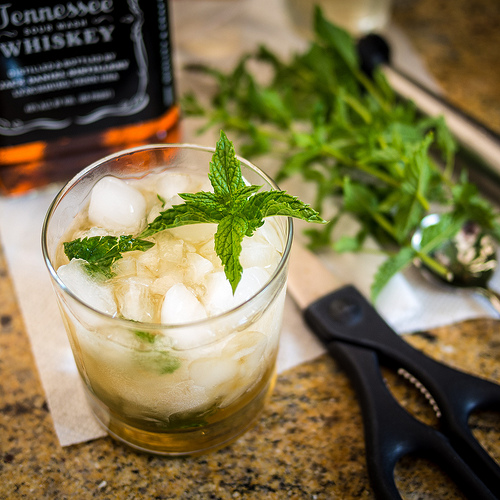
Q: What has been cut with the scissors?
A: Mint.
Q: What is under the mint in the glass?
A: Ice.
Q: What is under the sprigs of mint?
A: Paper.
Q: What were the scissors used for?
A: Cut peppermint.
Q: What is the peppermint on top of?
A: Ice cubes.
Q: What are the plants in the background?
A: Peppermint plants.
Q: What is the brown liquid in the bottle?
A: Whiskey.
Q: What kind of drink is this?
A: Whiskey on the rocks.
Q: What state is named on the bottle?
A: Tennessee.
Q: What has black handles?
A: Scissors.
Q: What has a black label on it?
A: Bottle.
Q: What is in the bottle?
A: Whiskey.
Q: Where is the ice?
A: In the glass.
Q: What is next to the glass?
A: Scissors.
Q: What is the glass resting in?
A: Granite counter.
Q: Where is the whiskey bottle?
A: Behind the glass.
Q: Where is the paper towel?
A: Beneath the glass.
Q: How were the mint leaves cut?
A: With the scissors.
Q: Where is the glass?
A: On the table.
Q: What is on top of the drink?
A: Mint.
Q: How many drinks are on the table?
A: One.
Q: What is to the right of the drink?
A: Scissors.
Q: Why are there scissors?
A: To cut the mint.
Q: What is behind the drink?
A: A bottle.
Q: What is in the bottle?
A: Whiskey.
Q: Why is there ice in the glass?
A: To chill the drink.